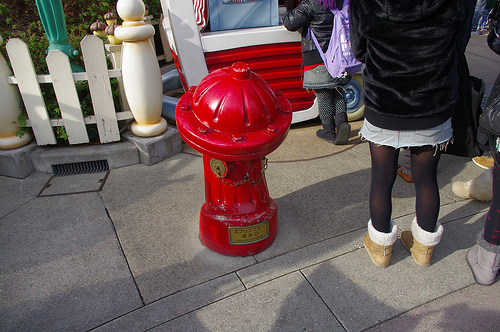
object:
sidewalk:
[1, 134, 499, 331]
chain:
[207, 158, 272, 187]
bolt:
[227, 130, 249, 143]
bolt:
[193, 126, 212, 136]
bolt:
[265, 123, 283, 135]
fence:
[0, 1, 167, 152]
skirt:
[355, 117, 457, 150]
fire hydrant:
[174, 59, 294, 257]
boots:
[361, 218, 443, 267]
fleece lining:
[366, 216, 444, 246]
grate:
[50, 158, 112, 178]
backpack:
[309, 0, 367, 79]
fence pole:
[111, 0, 171, 137]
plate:
[225, 221, 272, 245]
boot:
[466, 230, 499, 287]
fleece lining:
[474, 228, 498, 254]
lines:
[192, 0, 210, 32]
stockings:
[314, 87, 349, 124]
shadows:
[2, 152, 498, 331]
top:
[173, 60, 296, 164]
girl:
[286, 2, 360, 145]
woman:
[346, 0, 475, 268]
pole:
[34, 0, 87, 83]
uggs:
[314, 114, 355, 146]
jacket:
[346, 0, 478, 115]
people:
[280, 0, 499, 286]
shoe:
[396, 163, 414, 185]